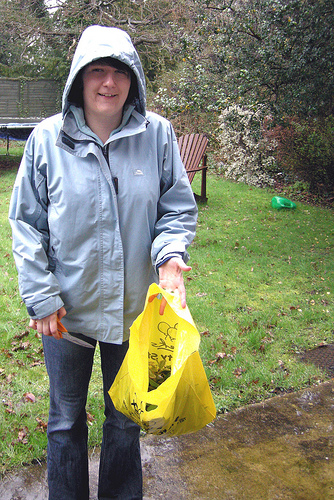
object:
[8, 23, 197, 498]
woman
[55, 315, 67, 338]
orange sissors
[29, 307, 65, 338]
hand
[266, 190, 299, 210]
cover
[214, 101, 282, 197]
bush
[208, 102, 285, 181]
flowers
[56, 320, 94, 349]
scissors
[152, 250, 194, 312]
hand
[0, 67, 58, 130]
fence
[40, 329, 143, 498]
jeans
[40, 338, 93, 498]
leg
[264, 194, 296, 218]
container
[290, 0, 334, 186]
trees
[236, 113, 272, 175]
bushes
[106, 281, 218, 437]
bag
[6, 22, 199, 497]
person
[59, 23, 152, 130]
gray hood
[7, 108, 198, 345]
jacket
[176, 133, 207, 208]
chair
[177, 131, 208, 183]
slats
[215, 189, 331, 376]
grass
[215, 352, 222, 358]
leaf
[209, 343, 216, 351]
leaf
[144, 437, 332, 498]
wet sidewlak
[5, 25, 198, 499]
girl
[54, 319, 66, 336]
handle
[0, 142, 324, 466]
yard